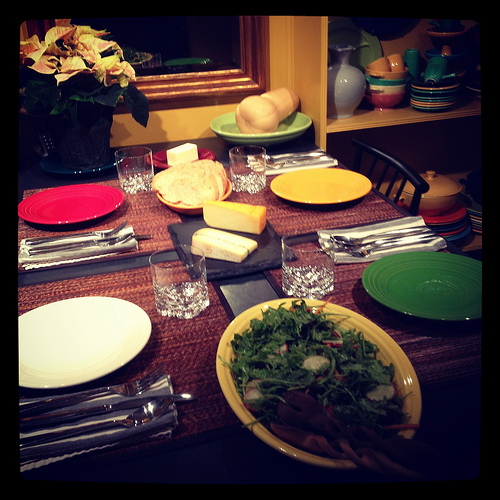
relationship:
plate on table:
[271, 168, 373, 205] [18, 135, 483, 484]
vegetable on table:
[236, 86, 301, 134] [18, 135, 483, 484]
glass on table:
[229, 145, 268, 194] [18, 135, 483, 484]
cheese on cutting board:
[192, 228, 259, 264] [167, 213, 298, 279]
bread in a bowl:
[152, 159, 227, 207] [157, 177, 234, 216]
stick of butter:
[166, 142, 198, 165] [166, 142, 200, 167]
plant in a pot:
[19, 19, 149, 128] [28, 106, 111, 170]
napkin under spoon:
[315, 214, 448, 266] [329, 224, 441, 258]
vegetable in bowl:
[236, 86, 301, 134] [211, 111, 312, 147]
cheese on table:
[192, 228, 259, 264] [18, 135, 483, 484]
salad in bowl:
[218, 295, 419, 447] [215, 297, 422, 470]